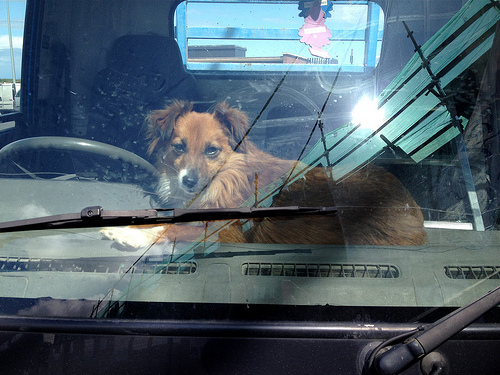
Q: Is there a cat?
A: No, there are no cats.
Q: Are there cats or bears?
A: No, there are no cats or bears.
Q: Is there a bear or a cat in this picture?
A: No, there are no cats or bears.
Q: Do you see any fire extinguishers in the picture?
A: No, there are no fire extinguishers.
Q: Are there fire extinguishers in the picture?
A: No, there are no fire extinguishers.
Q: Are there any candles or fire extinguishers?
A: No, there are no fire extinguishers or candles.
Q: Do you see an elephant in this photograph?
A: No, there are no elephants.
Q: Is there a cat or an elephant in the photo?
A: No, there are no elephants or cats.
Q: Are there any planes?
A: No, there are no planes.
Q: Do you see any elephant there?
A: No, there are no elephants.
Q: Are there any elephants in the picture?
A: No, there are no elephants.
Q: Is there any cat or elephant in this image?
A: No, there are no elephants or cats.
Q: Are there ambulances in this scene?
A: No, there are no ambulances.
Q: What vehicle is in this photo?
A: The vehicle is a car.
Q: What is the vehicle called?
A: The vehicle is a car.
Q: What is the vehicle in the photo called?
A: The vehicle is a car.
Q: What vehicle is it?
A: The vehicle is a car.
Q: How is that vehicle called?
A: This is a car.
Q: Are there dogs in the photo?
A: Yes, there is a dog.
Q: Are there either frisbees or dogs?
A: Yes, there is a dog.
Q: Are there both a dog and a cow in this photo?
A: No, there is a dog but no cows.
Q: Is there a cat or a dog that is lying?
A: Yes, the dog is lying.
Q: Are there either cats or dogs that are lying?
A: Yes, the dog is lying.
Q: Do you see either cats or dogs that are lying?
A: Yes, the dog is lying.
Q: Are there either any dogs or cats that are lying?
A: Yes, the dog is lying.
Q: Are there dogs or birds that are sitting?
A: Yes, the dog is sitting.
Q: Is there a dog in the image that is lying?
A: Yes, there is a dog that is lying.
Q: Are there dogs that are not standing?
A: Yes, there is a dog that is lying.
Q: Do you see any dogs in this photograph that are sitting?
A: Yes, there is a dog that is sitting.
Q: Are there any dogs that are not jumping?
A: Yes, there is a dog that is sitting.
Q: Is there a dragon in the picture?
A: No, there are no dragons.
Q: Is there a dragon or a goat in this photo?
A: No, there are no dragons or goats.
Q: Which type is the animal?
A: The animal is a dog.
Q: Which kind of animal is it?
A: The animal is a dog.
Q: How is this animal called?
A: This is a dog.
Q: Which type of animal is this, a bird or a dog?
A: This is a dog.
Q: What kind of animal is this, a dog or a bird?
A: This is a dog.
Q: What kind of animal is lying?
A: The animal is a dog.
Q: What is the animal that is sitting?
A: The animal is a dog.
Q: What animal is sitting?
A: The animal is a dog.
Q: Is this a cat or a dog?
A: This is a dog.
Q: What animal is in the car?
A: The animal is a dog.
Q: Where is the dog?
A: The dog is in the car.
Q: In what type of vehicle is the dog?
A: The dog is in the car.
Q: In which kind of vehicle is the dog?
A: The dog is in the car.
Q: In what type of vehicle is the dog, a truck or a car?
A: The dog is in a car.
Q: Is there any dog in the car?
A: Yes, there is a dog in the car.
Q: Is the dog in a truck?
A: No, the dog is in a car.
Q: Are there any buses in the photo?
A: No, there are no buses.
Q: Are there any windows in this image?
A: Yes, there is a window.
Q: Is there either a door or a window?
A: Yes, there is a window.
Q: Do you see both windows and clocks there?
A: No, there is a window but no clocks.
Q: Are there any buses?
A: No, there are no buses.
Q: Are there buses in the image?
A: No, there are no buses.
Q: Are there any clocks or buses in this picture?
A: No, there are no buses or clocks.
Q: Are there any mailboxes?
A: No, there are no mailboxes.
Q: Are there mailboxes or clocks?
A: No, there are no mailboxes or clocks.